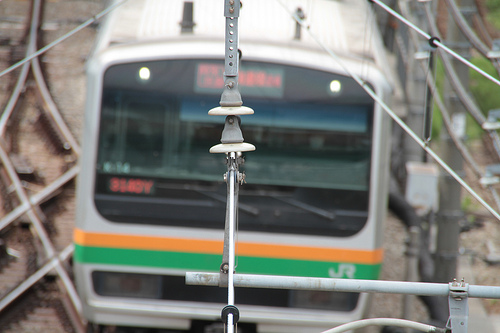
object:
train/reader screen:
[104, 174, 157, 196]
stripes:
[69, 224, 381, 264]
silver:
[222, 70, 237, 101]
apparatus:
[205, 0, 253, 274]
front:
[80, 38, 373, 331]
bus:
[71, 0, 391, 332]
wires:
[273, 1, 499, 221]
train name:
[191, 62, 284, 100]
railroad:
[0, 0, 82, 333]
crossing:
[0, 244, 76, 313]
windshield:
[96, 172, 369, 238]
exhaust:
[290, 4, 307, 40]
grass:
[427, 50, 495, 145]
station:
[0, 1, 499, 333]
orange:
[240, 245, 327, 255]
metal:
[232, 275, 449, 295]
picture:
[0, 1, 499, 332]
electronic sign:
[194, 60, 287, 101]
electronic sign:
[100, 177, 159, 195]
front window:
[97, 58, 374, 192]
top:
[86, 0, 395, 93]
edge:
[90, 200, 369, 239]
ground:
[0, 1, 499, 332]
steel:
[232, 274, 447, 296]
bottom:
[72, 264, 377, 332]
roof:
[88, 0, 394, 94]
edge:
[370, 80, 389, 278]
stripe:
[71, 242, 382, 279]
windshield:
[92, 58, 374, 192]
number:
[108, 176, 119, 193]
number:
[119, 177, 128, 192]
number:
[123, 177, 134, 192]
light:
[135, 64, 152, 81]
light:
[328, 77, 342, 95]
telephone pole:
[430, 1, 476, 320]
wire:
[372, 0, 499, 89]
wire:
[362, 5, 373, 86]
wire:
[419, 38, 435, 163]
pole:
[183, 270, 499, 300]